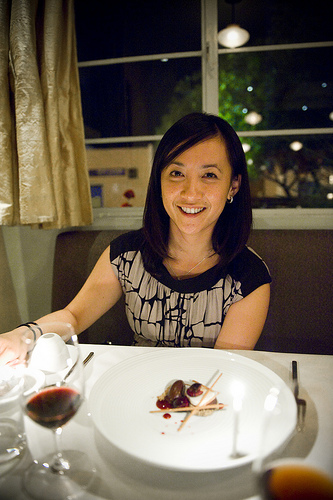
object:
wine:
[23, 385, 79, 427]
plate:
[88, 347, 299, 473]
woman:
[0, 111, 270, 353]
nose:
[182, 177, 202, 201]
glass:
[21, 319, 100, 498]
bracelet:
[23, 322, 43, 336]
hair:
[142, 111, 252, 265]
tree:
[157, 48, 273, 180]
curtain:
[0, 0, 94, 229]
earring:
[229, 196, 234, 203]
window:
[72, 0, 332, 212]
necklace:
[164, 238, 221, 263]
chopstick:
[65, 350, 94, 384]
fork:
[290, 361, 306, 427]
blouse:
[109, 229, 270, 348]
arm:
[213, 279, 270, 351]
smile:
[175, 202, 212, 217]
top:
[108, 225, 271, 346]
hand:
[0, 329, 27, 365]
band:
[26, 320, 43, 343]